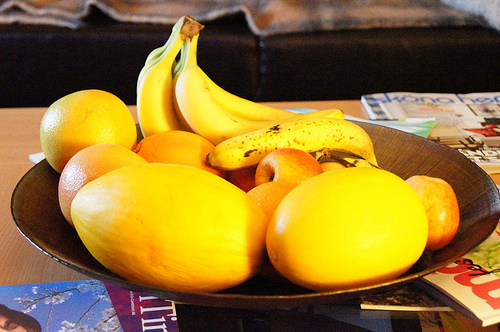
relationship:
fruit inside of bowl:
[38, 14, 459, 291] [11, 118, 498, 312]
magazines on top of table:
[0, 90, 499, 330] [1, 98, 498, 331]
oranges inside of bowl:
[40, 85, 225, 227] [11, 118, 498, 312]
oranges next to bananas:
[40, 85, 225, 227] [134, 14, 379, 171]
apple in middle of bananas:
[252, 146, 324, 187] [134, 14, 379, 171]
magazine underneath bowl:
[1, 278, 179, 331] [11, 118, 498, 312]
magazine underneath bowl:
[412, 185, 499, 328] [11, 118, 498, 312]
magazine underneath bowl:
[355, 280, 453, 312] [11, 118, 498, 312]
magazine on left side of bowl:
[1, 278, 179, 331] [11, 118, 498, 312]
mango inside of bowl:
[266, 164, 429, 291] [11, 118, 498, 312]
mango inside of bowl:
[64, 161, 267, 294] [11, 118, 498, 312]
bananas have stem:
[134, 14, 379, 171] [160, 12, 205, 70]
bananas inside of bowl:
[134, 14, 379, 171] [11, 118, 498, 312]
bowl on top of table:
[11, 118, 498, 312] [1, 98, 498, 331]